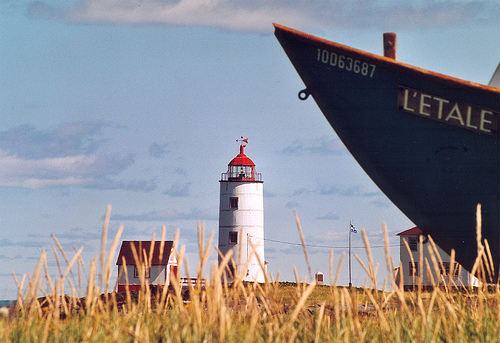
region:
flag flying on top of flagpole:
[346, 219, 362, 240]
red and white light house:
[210, 132, 275, 296]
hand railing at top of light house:
[220, 171, 268, 184]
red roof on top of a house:
[115, 236, 181, 272]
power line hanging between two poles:
[271, 233, 333, 252]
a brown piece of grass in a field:
[286, 200, 321, 289]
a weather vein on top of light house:
[228, 129, 256, 149]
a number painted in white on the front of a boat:
[309, 38, 388, 87]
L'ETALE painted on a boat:
[391, 73, 498, 140]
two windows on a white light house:
[225, 194, 243, 244]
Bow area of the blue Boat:
[269, 19, 499, 292]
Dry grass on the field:
[0, 204, 499, 341]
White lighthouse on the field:
[215, 129, 267, 286]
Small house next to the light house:
[112, 237, 182, 292]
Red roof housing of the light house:
[220, 132, 260, 182]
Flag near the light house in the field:
[344, 218, 361, 287]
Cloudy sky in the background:
[0, 0, 499, 289]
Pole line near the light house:
[244, 231, 419, 252]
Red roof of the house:
[112, 238, 182, 267]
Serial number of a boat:
[309, 44, 379, 83]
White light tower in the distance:
[201, 124, 279, 276]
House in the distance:
[109, 227, 186, 305]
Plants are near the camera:
[0, 202, 496, 337]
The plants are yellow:
[0, 205, 497, 340]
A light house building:
[216, 135, 263, 280]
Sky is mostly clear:
[0, 0, 497, 296]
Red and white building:
[115, 240, 180, 291]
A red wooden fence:
[177, 276, 204, 284]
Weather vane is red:
[235, 135, 246, 146]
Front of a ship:
[270, 21, 496, 284]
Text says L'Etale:
[401, 86, 491, 131]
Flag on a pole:
[348, 224, 356, 286]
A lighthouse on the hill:
[218, 135, 265, 281]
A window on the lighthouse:
[229, 194, 238, 211]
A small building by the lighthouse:
[118, 239, 178, 282]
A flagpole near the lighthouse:
[348, 220, 357, 283]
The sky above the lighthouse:
[1, 0, 499, 294]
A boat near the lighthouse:
[273, 23, 498, 289]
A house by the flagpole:
[398, 225, 478, 288]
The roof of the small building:
[118, 240, 172, 262]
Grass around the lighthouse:
[0, 291, 499, 339]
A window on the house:
[408, 237, 419, 253]